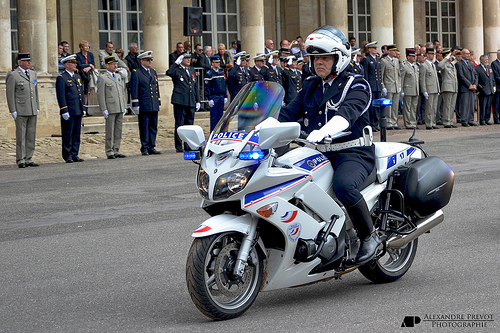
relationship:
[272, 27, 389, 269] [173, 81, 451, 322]
policeman on motorcycle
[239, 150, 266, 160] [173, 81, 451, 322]
light on motorcycle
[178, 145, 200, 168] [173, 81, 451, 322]
light on motorcycle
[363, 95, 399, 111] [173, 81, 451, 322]
light on motorcycle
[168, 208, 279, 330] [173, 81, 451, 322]
tire on motorcycle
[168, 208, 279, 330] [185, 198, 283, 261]
tire has cover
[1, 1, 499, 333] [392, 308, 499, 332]
photo has watermark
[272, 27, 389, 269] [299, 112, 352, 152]
policeman has glove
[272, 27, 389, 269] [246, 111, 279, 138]
policeman has glove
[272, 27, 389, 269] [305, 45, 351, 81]
policeman has head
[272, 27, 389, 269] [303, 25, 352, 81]
policeman has helmet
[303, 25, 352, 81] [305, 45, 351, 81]
helmet on head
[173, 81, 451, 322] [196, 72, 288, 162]
motorcycle has shield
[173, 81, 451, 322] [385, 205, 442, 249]
motorcycle has pipe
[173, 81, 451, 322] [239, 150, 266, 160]
motorcycle has light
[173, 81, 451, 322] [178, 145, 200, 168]
motorcycle has light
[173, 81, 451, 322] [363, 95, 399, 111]
motorcycle has light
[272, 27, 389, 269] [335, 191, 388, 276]
policeman wearing boots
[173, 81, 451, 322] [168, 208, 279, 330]
motorcycle has tire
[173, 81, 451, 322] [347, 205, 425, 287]
motorcycle has tire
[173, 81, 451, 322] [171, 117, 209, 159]
motorcycle has mirror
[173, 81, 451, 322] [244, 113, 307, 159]
motorcycle has mirror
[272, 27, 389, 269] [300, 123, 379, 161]
policeman has belt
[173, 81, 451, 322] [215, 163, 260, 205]
motorcycle has headlight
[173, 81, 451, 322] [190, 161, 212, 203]
motorcycle has headlight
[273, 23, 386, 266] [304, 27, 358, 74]
policeman wearing helmet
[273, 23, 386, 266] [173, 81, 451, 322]
policeman on motorcycle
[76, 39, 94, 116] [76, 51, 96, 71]
woman in jacket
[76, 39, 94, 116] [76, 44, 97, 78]
woman in jacket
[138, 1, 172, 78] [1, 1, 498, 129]
column of building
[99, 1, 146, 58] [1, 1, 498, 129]
window of building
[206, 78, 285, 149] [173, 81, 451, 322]
shield of motorcycle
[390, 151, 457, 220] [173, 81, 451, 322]
box on motorcycle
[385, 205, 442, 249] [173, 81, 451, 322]
pipe on motorcycle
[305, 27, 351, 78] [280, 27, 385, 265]
helmet on policeman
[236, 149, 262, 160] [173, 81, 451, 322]
light on motorcycle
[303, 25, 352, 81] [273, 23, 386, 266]
helmet worn by policeman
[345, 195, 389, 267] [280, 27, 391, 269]
boot worn by motorcyclist